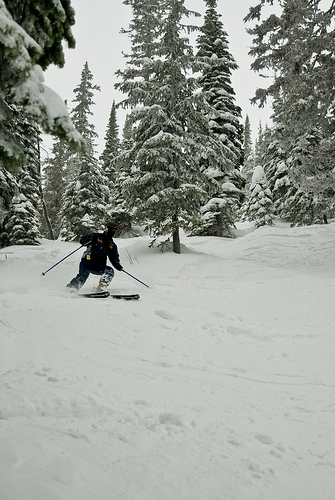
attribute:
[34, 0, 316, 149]
sky — grey, overcast, cloudy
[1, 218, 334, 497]
ski slope — white, snowy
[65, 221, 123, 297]
man — skiing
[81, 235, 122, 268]
jacket — black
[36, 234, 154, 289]
ski poles — blue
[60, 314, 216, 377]
snow — drifts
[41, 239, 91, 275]
ski pole — blue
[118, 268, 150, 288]
ski pole — blue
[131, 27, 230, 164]
trees — snowy, forest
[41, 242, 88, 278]
pole — ski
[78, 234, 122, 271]
ski jacket — black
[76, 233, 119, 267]
jacket — black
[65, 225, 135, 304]
skier — rushing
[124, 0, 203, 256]
pine tree — very tall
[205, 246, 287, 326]
snow — bench covered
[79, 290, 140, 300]
skis — pair, black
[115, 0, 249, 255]
tree — dead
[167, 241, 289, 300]
snow — white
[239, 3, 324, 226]
trees — pine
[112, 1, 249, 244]
trees — pine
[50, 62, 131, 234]
trees — pine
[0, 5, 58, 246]
trees — pine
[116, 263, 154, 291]
pole — ski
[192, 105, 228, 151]
branch — pine, tree